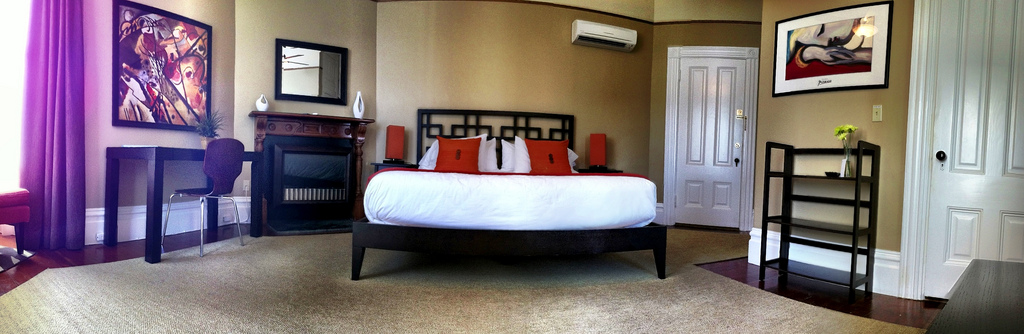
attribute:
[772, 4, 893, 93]
artwork — framed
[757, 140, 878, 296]
shelf — wooden 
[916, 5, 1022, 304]
door — white, wooden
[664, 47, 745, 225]
door — white, wooden